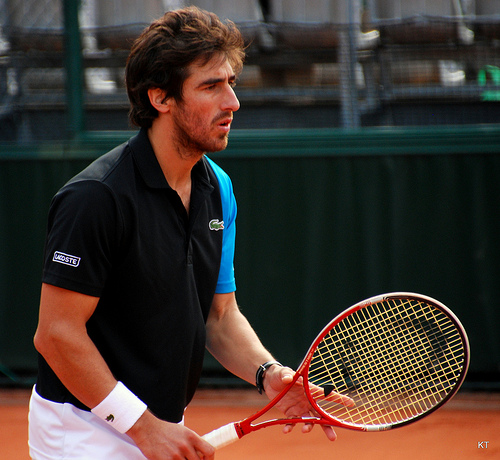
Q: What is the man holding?
A: Tennis racket.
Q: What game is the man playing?
A: Tennis.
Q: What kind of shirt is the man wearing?
A: Short sleeved.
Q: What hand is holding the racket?
A: Right.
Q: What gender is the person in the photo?
A: Male.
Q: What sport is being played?
A: Tennis.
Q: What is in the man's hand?
A: Tennis racket.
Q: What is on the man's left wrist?
A: A watch.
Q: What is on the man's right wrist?
A: A wristband.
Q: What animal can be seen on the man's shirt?
A: A crocodile.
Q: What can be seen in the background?
A: Chairs.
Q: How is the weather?
A: Sunny.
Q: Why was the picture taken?
A: To capture the tennis player.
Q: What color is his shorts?
A: White.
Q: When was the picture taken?
A: During a tennis match.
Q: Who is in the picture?
A: A man.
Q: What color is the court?
A: Brown.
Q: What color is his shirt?
A: Blue and navy blue.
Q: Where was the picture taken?
A: On a tennis court.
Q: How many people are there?
A: 1.